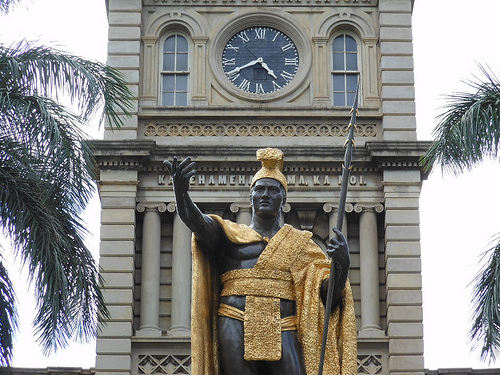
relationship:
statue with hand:
[153, 73, 379, 375] [160, 156, 200, 187]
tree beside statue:
[1, 28, 140, 374] [153, 73, 379, 375]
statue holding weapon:
[153, 73, 379, 375] [315, 71, 361, 375]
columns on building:
[135, 200, 387, 341] [94, 1, 435, 373]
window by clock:
[155, 29, 193, 109] [214, 12, 305, 99]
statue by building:
[153, 73, 379, 375] [94, 1, 435, 373]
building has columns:
[94, 1, 435, 373] [135, 200, 387, 341]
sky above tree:
[2, 1, 108, 65] [1, 28, 140, 374]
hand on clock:
[226, 55, 263, 75] [214, 12, 305, 99]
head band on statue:
[247, 143, 293, 193] [153, 73, 379, 375]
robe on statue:
[186, 215, 369, 373] [153, 73, 379, 375]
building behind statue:
[94, 1, 435, 373] [153, 73, 379, 375]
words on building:
[155, 172, 368, 187] [94, 1, 435, 373]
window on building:
[155, 29, 193, 109] [94, 1, 435, 373]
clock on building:
[214, 12, 305, 99] [94, 1, 435, 373]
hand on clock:
[257, 56, 278, 81] [214, 12, 305, 99]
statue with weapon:
[153, 73, 379, 375] [315, 71, 361, 375]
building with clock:
[94, 1, 435, 373] [214, 12, 305, 99]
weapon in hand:
[315, 71, 361, 375] [319, 225, 356, 272]